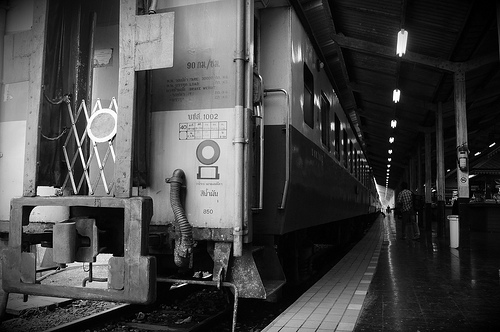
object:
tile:
[269, 317, 289, 327]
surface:
[318, 263, 407, 329]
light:
[390, 119, 397, 128]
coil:
[165, 169, 199, 269]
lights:
[387, 164, 391, 168]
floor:
[290, 286, 497, 329]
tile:
[323, 315, 342, 323]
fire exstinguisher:
[456, 142, 469, 172]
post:
[436, 102, 448, 239]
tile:
[313, 306, 331, 314]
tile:
[291, 313, 309, 321]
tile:
[347, 303, 363, 309]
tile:
[364, 266, 376, 275]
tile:
[340, 265, 348, 272]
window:
[361, 161, 364, 184]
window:
[354, 148, 357, 178]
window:
[349, 140, 353, 174]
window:
[343, 128, 348, 168]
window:
[358, 155, 360, 182]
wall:
[283, 11, 372, 207]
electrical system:
[140, 108, 255, 244]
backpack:
[406, 188, 425, 210]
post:
[423, 132, 434, 232]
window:
[334, 112, 341, 161]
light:
[389, 137, 395, 143]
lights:
[386, 184, 389, 186]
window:
[303, 62, 314, 130]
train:
[0, 0, 382, 332]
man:
[397, 181, 422, 240]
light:
[388, 149, 393, 154]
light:
[386, 179, 389, 182]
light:
[386, 177, 389, 179]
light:
[386, 181, 388, 183]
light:
[386, 173, 390, 176]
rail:
[263, 88, 289, 210]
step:
[230, 245, 287, 300]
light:
[388, 158, 392, 163]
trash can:
[446, 214, 459, 248]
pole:
[454, 62, 470, 234]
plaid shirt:
[396, 189, 413, 213]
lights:
[386, 169, 389, 172]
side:
[242, 0, 379, 235]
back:
[0, 0, 263, 332]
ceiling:
[327, 0, 467, 190]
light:
[392, 88, 401, 103]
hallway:
[340, 257, 474, 305]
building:
[290, 0, 500, 332]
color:
[315, 282, 357, 320]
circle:
[196, 140, 221, 165]